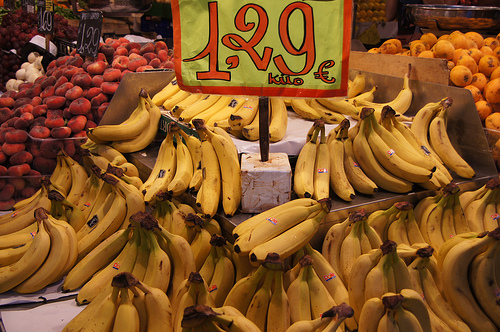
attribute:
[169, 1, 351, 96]
sign — yellow, for bananas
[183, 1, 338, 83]
price — printed in orange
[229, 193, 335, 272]
bananas — in a bunch, toppling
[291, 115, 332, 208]
bananas — in a bunch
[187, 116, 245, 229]
bananas — in a bunch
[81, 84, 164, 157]
bananas — in a bunch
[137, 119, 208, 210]
bananas — in a bunch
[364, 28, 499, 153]
oranges — a bit grimy, orange, maybe clementines, a bit banged up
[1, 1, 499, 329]
fruit — various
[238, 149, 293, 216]
block — cube, grungy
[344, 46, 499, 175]
divider — cardboard, brown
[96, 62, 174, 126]
divider — cardboard, brown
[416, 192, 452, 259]
banana — ripe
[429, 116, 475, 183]
banana — ripe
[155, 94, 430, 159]
paper — white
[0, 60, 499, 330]
bananas — for sale, in three rows, yellow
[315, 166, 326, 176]
sticker — dole sticker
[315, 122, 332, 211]
banana — ripe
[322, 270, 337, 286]
sticker — dole sticker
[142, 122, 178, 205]
banana — ripe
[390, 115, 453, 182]
banana — ripe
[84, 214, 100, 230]
sticker — black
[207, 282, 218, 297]
sticker — dole sticker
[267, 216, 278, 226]
sticker — dole sticker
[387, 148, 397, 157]
sticker — dole sticker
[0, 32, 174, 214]
peaches — saturn peaches, also donut peaches, not all that exotic, red, peach, yellow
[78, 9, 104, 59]
sign — blackboard, black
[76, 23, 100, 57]
price — in white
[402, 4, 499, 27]
bowl — silvertone metal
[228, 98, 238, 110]
sticker — black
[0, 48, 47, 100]
fruit — likely not onions, not sold w/ onions!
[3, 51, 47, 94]
pears — a bit more likely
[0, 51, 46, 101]
coconuts — most likely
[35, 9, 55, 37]
sign — black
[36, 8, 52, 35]
price — in white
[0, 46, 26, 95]
plums — dark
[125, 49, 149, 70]
peach — large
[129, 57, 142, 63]
bruise — slight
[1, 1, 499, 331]
scene — indoors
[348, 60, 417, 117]
bananas — singles